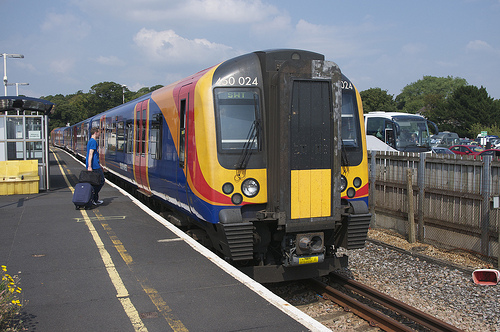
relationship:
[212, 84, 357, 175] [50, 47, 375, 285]
windscreen on commuter train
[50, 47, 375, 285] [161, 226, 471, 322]
commuter train on railway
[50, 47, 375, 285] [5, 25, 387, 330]
commuter train at station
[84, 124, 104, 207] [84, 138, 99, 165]
man wearing shirt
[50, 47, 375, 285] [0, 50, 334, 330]
commuter train at station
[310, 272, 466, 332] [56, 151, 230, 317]
railway next to sidewalk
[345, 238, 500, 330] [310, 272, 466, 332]
rocks are on railway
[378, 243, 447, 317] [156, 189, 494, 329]
rocks around track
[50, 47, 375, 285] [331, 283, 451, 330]
commuter train on track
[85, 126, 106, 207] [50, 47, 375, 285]
man boarding commuter train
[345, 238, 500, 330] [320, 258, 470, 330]
rocks are by tracks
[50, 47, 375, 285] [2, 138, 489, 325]
commuter train at station